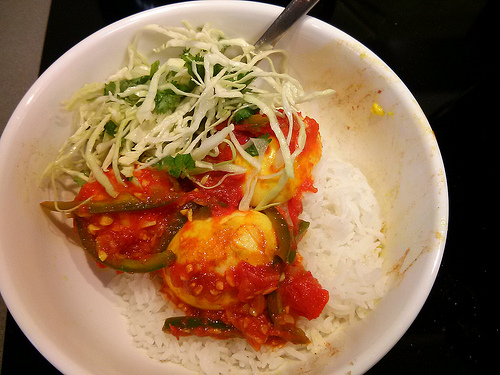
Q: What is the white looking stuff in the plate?
A: Rice.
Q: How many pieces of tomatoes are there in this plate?
A: Three.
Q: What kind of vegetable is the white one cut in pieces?
A: Cabbage.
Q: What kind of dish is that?
A: Rice and vegetable sauce.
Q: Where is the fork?
A: On the side of the plate.